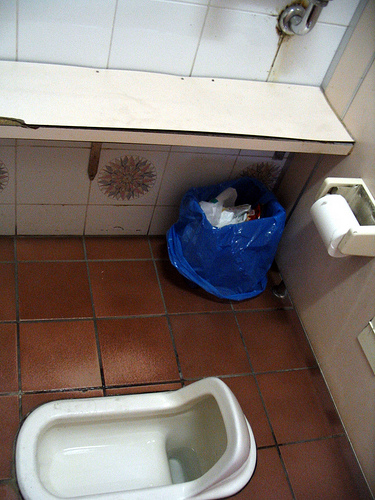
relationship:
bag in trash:
[166, 176, 287, 299] [201, 185, 263, 227]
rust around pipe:
[276, 3, 306, 35] [273, 0, 331, 35]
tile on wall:
[19, 4, 352, 83] [2, 0, 373, 86]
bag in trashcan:
[164, 176, 287, 301] [183, 173, 283, 295]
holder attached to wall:
[314, 176, 373, 256] [270, 0, 373, 499]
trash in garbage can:
[219, 202, 237, 215] [167, 177, 286, 302]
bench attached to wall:
[0, 55, 355, 158] [1, 0, 361, 235]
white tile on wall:
[189, 7, 284, 82] [1, 0, 361, 235]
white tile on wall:
[268, 16, 346, 86] [1, 0, 361, 235]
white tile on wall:
[104, 0, 207, 77] [1, 0, 361, 235]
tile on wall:
[17, 0, 114, 69] [1, 0, 361, 235]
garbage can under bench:
[167, 177, 286, 302] [0, 55, 355, 158]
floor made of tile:
[1, 235, 362, 498] [94, 311, 184, 389]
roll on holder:
[310, 192, 360, 256] [314, 176, 373, 256]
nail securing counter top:
[209, 78, 215, 81] [0, 57, 357, 157]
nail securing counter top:
[180, 76, 184, 80] [0, 57, 357, 157]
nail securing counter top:
[94, 68, 100, 72] [0, 57, 357, 157]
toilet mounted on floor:
[13, 379, 261, 495] [1, 235, 362, 498]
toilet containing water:
[13, 372, 259, 500] [166, 445, 203, 484]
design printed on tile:
[95, 153, 158, 202] [86, 146, 169, 205]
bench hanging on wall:
[0, 55, 355, 158] [84, 1, 340, 85]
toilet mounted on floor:
[13, 372, 259, 500] [1, 235, 362, 498]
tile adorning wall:
[100, 158, 156, 209] [1, 0, 361, 235]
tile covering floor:
[87, 257, 166, 314] [1, 235, 362, 498]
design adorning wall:
[95, 153, 158, 202] [1, 0, 361, 235]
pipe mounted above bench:
[278, 0, 331, 38] [0, 55, 357, 163]